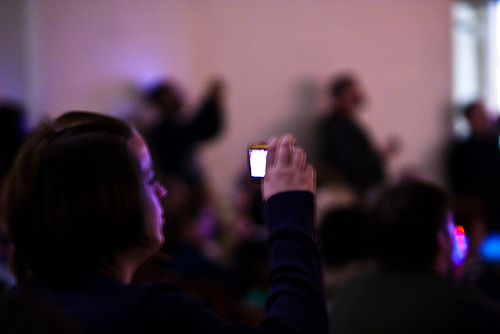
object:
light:
[253, 156, 266, 174]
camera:
[247, 145, 271, 180]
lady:
[1, 109, 318, 332]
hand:
[262, 133, 318, 199]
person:
[314, 59, 392, 184]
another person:
[143, 69, 228, 189]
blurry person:
[445, 100, 497, 192]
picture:
[2, 2, 496, 333]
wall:
[8, 3, 324, 68]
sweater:
[3, 188, 329, 334]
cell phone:
[209, 68, 224, 87]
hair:
[0, 111, 139, 282]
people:
[11, 56, 495, 320]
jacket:
[320, 112, 383, 180]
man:
[323, 176, 497, 332]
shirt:
[331, 273, 496, 332]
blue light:
[480, 229, 500, 263]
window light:
[450, 2, 500, 116]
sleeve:
[252, 191, 331, 332]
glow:
[147, 165, 169, 230]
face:
[124, 130, 172, 257]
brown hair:
[463, 98, 481, 120]